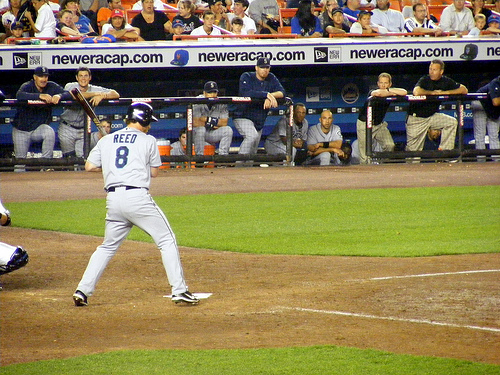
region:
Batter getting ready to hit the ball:
[44, 78, 211, 318]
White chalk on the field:
[343, 275, 437, 344]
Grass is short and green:
[270, 178, 365, 277]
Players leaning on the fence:
[346, 63, 465, 168]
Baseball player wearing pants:
[57, 176, 231, 326]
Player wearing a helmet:
[118, 94, 165, 138]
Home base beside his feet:
[160, 275, 210, 313]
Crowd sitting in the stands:
[68, 6, 267, 46]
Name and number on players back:
[94, 114, 147, 184]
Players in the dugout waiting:
[357, 53, 497, 182]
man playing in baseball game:
[0, 13, 494, 363]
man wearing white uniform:
[63, 113, 221, 327]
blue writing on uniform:
[96, 114, 150, 196]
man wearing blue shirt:
[217, 58, 287, 119]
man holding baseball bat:
[44, 70, 174, 192]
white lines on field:
[205, 204, 497, 363]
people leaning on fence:
[2, 34, 498, 205]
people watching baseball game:
[1, 0, 491, 79]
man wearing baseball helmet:
[110, 95, 170, 142]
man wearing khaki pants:
[388, 112, 460, 148]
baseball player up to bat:
[62, 83, 202, 313]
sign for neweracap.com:
[51, 43, 168, 72]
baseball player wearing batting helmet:
[119, 100, 160, 133]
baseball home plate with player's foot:
[162, 284, 219, 304]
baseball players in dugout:
[18, 52, 478, 167]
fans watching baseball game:
[1, 7, 493, 44]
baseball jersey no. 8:
[86, 128, 163, 185]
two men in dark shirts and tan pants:
[356, 59, 469, 171]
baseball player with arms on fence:
[233, 57, 288, 169]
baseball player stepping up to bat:
[66, 85, 204, 309]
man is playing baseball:
[25, 79, 257, 319]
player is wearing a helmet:
[116, 87, 175, 134]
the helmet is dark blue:
[115, 93, 173, 125]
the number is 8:
[94, 130, 145, 178]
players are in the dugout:
[10, 55, 465, 172]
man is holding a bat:
[45, 71, 164, 170]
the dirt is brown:
[205, 249, 392, 343]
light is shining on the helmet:
[122, 97, 154, 125]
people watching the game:
[134, 2, 441, 52]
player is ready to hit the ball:
[20, 80, 240, 325]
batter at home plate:
[67, 88, 198, 304]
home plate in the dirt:
[169, 290, 209, 299]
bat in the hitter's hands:
[72, 85, 107, 137]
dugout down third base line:
[4, 41, 499, 163]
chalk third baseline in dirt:
[363, 265, 497, 283]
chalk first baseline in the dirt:
[265, 301, 495, 331]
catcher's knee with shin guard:
[2, 248, 29, 275]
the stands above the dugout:
[3, 2, 498, 39]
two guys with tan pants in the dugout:
[356, 54, 466, 162]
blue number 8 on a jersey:
[115, 145, 127, 167]